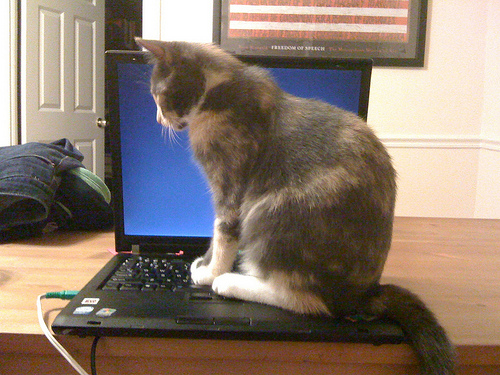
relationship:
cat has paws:
[121, 27, 450, 332] [185, 255, 238, 290]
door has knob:
[20, 4, 110, 143] [95, 116, 113, 130]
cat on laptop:
[121, 27, 450, 332] [39, 35, 412, 338]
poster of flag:
[205, 3, 433, 72] [230, 4, 412, 47]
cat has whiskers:
[121, 27, 450, 332] [155, 117, 185, 148]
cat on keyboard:
[121, 27, 450, 332] [83, 252, 240, 293]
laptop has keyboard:
[39, 35, 412, 338] [83, 252, 240, 293]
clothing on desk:
[4, 139, 117, 244] [14, 212, 492, 365]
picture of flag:
[205, 3, 433, 72] [230, 4, 412, 47]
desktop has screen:
[39, 35, 412, 338] [111, 62, 360, 230]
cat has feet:
[121, 27, 450, 332] [191, 256, 284, 307]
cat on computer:
[121, 27, 450, 332] [39, 35, 412, 338]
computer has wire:
[39, 35, 412, 338] [83, 339, 105, 374]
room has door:
[33, 12, 492, 357] [20, 4, 110, 143]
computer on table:
[39, 35, 412, 338] [14, 212, 492, 365]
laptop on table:
[39, 35, 412, 338] [14, 212, 492, 365]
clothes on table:
[4, 139, 117, 244] [14, 212, 492, 365]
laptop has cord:
[39, 35, 412, 338] [46, 287, 79, 301]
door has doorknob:
[20, 4, 110, 143] [96, 115, 115, 137]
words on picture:
[268, 43, 345, 55] [205, 3, 433, 72]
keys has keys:
[83, 252, 240, 293] [137, 271, 171, 283]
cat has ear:
[121, 27, 450, 332] [128, 34, 173, 65]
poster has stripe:
[205, 3, 433, 72] [228, 12, 411, 30]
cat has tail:
[121, 27, 450, 332] [370, 283, 461, 371]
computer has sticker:
[39, 35, 412, 338] [82, 295, 102, 307]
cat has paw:
[121, 27, 450, 332] [192, 267, 218, 292]